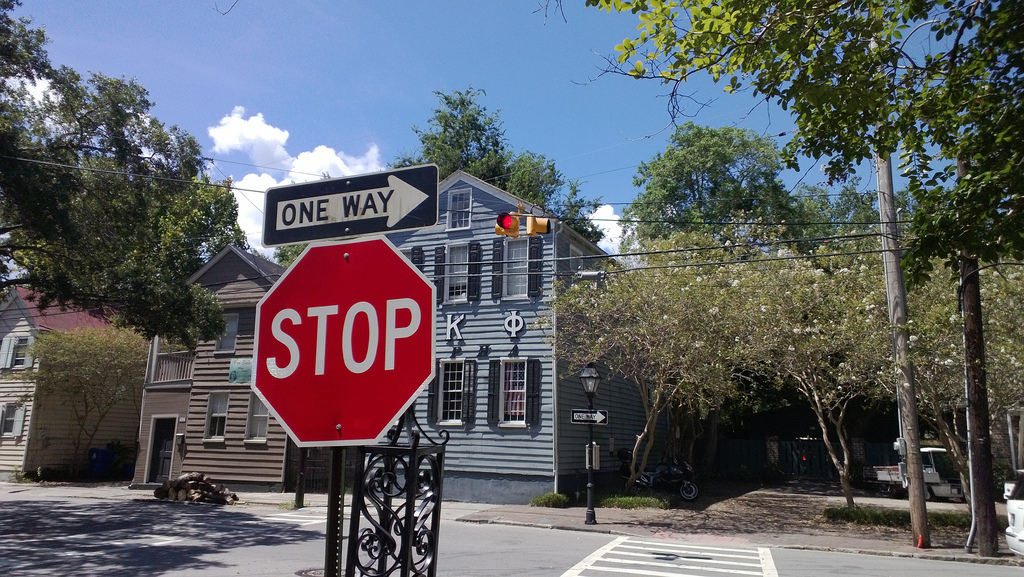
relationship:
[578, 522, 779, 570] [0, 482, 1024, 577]
lines painted on a ground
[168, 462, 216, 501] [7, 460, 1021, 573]
fire wood on ground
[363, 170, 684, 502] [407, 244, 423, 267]
building with shutters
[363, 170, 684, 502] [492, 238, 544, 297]
building with shutters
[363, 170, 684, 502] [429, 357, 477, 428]
building with shutters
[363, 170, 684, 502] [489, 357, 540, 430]
building with shutters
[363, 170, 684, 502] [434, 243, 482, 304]
building with shutters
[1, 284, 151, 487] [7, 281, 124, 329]
building with roof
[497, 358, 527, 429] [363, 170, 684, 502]
window on a building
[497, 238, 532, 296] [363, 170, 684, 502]
window on a building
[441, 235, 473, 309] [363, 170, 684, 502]
window on a building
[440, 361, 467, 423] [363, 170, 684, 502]
window on a building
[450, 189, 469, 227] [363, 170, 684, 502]
window on a building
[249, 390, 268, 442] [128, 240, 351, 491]
window on a building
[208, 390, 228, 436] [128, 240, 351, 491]
window on a building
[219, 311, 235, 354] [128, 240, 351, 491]
window on a building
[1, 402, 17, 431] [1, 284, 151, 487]
window on a building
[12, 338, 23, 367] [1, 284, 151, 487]
window on a building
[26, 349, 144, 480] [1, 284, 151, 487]
wall on side of a building